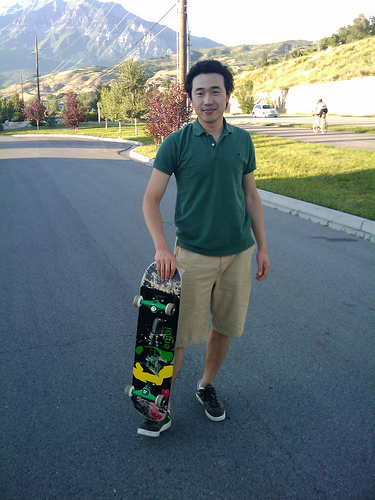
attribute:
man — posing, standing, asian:
[138, 60, 271, 446]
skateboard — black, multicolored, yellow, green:
[136, 261, 180, 423]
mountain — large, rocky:
[1, 3, 225, 79]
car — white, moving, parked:
[254, 101, 283, 121]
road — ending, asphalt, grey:
[0, 135, 373, 497]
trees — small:
[0, 62, 188, 143]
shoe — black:
[194, 380, 228, 423]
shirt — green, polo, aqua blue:
[151, 123, 261, 254]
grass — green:
[254, 138, 366, 202]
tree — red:
[62, 89, 89, 133]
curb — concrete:
[291, 199, 375, 257]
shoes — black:
[135, 390, 235, 437]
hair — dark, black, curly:
[178, 62, 238, 99]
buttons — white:
[203, 132, 218, 150]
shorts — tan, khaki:
[173, 242, 255, 343]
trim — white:
[141, 419, 178, 437]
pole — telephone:
[172, 0, 193, 120]